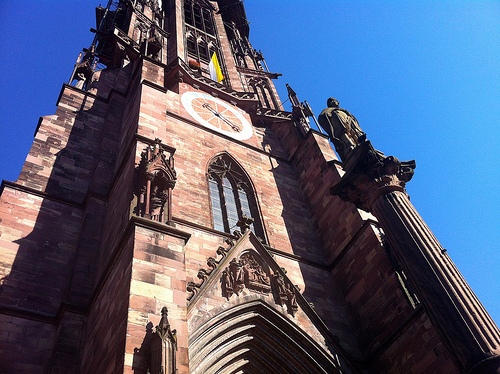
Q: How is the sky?
A: Clear and blue.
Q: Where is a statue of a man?
A: Atop a column.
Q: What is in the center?
A: A building.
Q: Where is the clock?
A: On the building's front.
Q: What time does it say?
A: Ten twenty five.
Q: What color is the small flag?
A: Yellow and white.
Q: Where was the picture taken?
A: Outside a church.